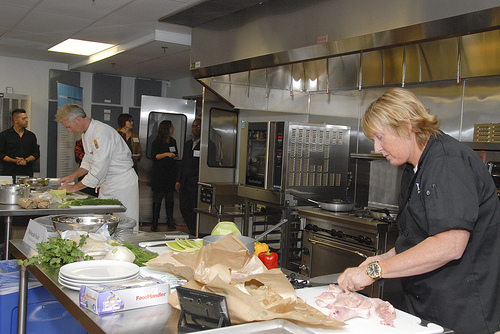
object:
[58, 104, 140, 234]
chef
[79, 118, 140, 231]
white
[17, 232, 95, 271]
green lettuce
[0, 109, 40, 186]
man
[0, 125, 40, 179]
all black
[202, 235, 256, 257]
mixing bowl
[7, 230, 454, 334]
table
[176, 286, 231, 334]
ipod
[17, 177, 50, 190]
food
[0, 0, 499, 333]
kitchen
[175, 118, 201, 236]
staff person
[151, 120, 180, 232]
staff person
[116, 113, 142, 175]
staff person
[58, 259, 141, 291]
plate stack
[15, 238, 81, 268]
leaves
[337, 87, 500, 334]
man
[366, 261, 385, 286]
watch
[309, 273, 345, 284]
knife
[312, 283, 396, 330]
meat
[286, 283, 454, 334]
cutting board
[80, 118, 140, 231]
outfit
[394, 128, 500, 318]
outfit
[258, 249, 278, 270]
pepper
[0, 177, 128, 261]
table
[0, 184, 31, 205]
pot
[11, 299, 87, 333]
trasn can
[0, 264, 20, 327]
ground